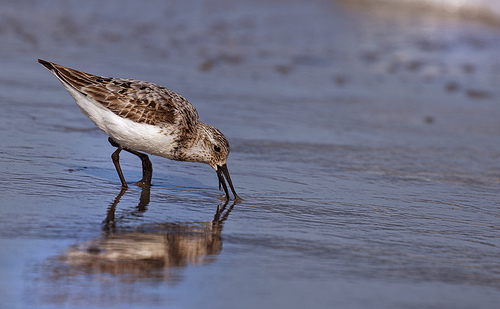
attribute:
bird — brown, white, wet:
[40, 49, 248, 209]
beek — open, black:
[199, 163, 242, 207]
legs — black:
[94, 158, 160, 192]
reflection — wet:
[65, 230, 226, 280]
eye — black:
[207, 140, 230, 170]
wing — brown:
[61, 70, 176, 123]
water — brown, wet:
[374, 126, 422, 168]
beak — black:
[216, 164, 242, 198]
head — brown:
[190, 114, 240, 206]